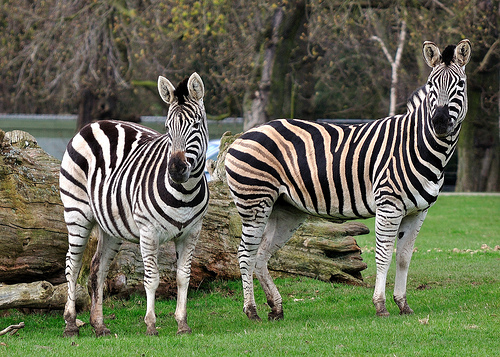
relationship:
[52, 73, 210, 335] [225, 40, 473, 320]
zebra next to zebra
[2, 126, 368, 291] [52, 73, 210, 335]
tree trunk behind zebra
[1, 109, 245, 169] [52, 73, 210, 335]
water behind zebra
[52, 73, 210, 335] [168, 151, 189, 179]
zebra has nose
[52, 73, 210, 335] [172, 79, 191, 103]
zebra has hair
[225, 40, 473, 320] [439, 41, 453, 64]
zebra has hair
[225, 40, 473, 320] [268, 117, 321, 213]
zebra has stripe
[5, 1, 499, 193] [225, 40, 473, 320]
forest behind zebra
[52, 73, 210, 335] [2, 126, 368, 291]
zebra in front of tree trunk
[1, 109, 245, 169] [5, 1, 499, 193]
water beside forest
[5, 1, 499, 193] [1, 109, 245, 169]
forest next to water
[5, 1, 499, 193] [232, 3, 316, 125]
forest has tree